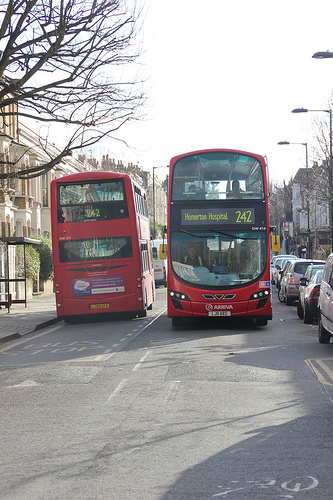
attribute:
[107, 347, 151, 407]
lines — white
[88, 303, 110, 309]
license plate — black, yellow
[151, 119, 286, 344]
bus — double decker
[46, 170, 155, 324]
bus — double decker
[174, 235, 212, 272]
driver — male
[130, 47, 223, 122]
sky — blue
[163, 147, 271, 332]
bus — red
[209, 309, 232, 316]
license plate — black, white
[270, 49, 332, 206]
lights — three, street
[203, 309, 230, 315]
license plate — white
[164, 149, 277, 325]
bus — double decker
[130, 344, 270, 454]
street — along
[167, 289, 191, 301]
lump — head